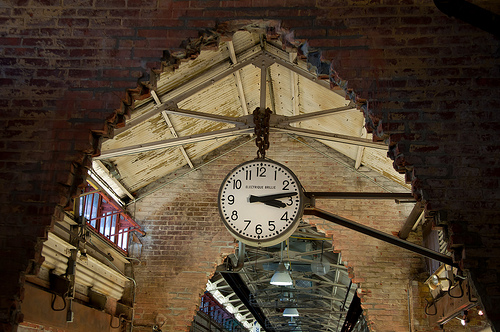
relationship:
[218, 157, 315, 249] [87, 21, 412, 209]
clock hanging from ceiling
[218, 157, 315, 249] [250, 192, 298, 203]
clock has a hand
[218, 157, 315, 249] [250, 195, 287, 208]
clock has a hand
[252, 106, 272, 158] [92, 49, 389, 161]
chain hanging from a beam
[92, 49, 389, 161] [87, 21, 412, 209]
beam on ceiling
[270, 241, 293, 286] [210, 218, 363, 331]
ceiling light hanging from ceiling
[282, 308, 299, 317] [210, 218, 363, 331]
ceiling light hanging from ceiling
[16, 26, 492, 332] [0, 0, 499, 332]
entrance cut into wall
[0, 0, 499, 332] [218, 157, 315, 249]
building contains clock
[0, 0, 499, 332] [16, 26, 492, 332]
building has an entrance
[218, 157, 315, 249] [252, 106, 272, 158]
clock hanging from chain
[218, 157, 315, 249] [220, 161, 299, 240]
clock has a face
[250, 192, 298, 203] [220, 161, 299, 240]
hand on face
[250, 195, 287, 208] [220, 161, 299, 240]
hand on face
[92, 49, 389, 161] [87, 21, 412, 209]
beam holding up ceiling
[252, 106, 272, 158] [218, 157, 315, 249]
chain holds clock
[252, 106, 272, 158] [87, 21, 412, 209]
chain on ceiling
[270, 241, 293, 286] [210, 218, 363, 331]
ceiling light hangs from ceiling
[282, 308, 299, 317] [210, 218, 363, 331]
ceiling light hangs from ceiling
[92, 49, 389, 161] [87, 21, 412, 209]
beam supports ceiling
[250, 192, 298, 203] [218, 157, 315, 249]
hand on clock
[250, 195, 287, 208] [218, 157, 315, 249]
hand on clock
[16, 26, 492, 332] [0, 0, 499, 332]
entrance in wall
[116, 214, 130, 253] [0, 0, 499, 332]
window on building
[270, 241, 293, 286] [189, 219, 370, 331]
ceiling light in opening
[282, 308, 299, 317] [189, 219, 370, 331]
ceiling light in opening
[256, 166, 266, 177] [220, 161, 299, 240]
number on face